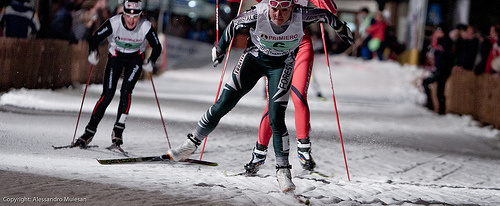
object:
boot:
[68, 128, 99, 148]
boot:
[111, 125, 125, 145]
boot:
[165, 138, 198, 162]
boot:
[243, 147, 266, 174]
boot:
[274, 165, 295, 191]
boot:
[296, 142, 316, 169]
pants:
[251, 36, 311, 154]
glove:
[335, 28, 356, 45]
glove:
[210, 44, 224, 63]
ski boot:
[164, 142, 203, 165]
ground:
[0, 35, 496, 206]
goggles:
[267, 1, 292, 9]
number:
[270, 42, 288, 52]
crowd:
[331, 4, 500, 114]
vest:
[249, 0, 304, 57]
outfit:
[52, 15, 184, 157]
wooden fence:
[0, 34, 162, 99]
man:
[158, 0, 355, 193]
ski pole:
[317, 17, 364, 204]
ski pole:
[69, 59, 100, 143]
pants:
[184, 52, 295, 168]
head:
[121, 0, 144, 29]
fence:
[383, 45, 500, 133]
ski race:
[0, 0, 500, 205]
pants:
[82, 53, 143, 140]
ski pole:
[141, 68, 172, 151]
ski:
[97, 156, 218, 166]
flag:
[310, 0, 337, 16]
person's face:
[267, 8, 288, 28]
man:
[244, 0, 338, 174]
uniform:
[88, 11, 163, 139]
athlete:
[51, 2, 177, 156]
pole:
[208, 4, 222, 62]